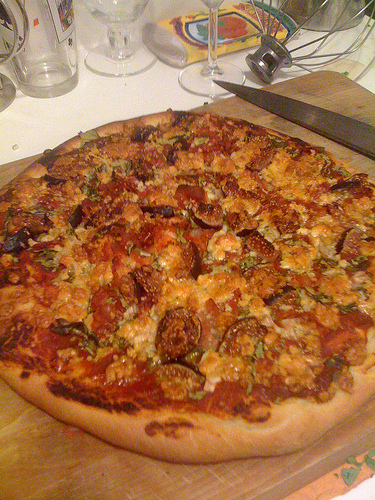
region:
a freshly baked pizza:
[0, 84, 372, 492]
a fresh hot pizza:
[1, 98, 373, 482]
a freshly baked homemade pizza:
[0, 90, 373, 486]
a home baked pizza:
[1, 71, 370, 485]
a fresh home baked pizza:
[2, 96, 371, 483]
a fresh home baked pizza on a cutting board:
[1, 109, 373, 481]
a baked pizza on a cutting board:
[0, 104, 372, 493]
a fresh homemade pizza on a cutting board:
[0, 99, 373, 462]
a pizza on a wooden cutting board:
[0, 109, 373, 477]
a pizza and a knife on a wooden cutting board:
[1, 53, 371, 440]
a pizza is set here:
[7, 111, 365, 463]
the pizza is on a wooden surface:
[4, 53, 365, 492]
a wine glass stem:
[180, 2, 247, 98]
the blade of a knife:
[212, 74, 369, 162]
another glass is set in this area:
[84, 0, 158, 75]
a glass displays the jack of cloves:
[10, 5, 79, 105]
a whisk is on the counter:
[248, 3, 371, 78]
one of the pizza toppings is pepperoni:
[96, 271, 198, 359]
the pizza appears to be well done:
[43, 162, 344, 383]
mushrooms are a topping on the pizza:
[185, 198, 229, 239]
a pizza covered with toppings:
[28, 233, 364, 407]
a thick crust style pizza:
[16, 353, 355, 467]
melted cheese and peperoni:
[102, 260, 262, 371]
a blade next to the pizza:
[211, 67, 370, 154]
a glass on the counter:
[14, 1, 95, 91]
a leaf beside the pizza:
[322, 449, 373, 482]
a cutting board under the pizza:
[18, 407, 273, 498]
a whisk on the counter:
[251, 3, 345, 83]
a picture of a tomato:
[150, 6, 272, 61]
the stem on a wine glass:
[203, 2, 235, 105]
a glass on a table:
[74, 7, 160, 96]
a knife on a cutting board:
[215, 59, 373, 144]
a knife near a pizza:
[207, 59, 343, 166]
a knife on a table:
[192, 46, 367, 211]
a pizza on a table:
[41, 68, 363, 449]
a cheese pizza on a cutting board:
[41, 166, 286, 427]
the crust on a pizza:
[55, 348, 311, 449]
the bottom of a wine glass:
[184, 20, 256, 89]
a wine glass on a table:
[169, 1, 259, 118]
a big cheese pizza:
[23, 91, 355, 444]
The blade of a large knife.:
[210, 69, 373, 152]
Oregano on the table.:
[339, 449, 373, 485]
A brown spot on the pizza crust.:
[136, 414, 196, 440]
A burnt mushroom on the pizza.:
[147, 303, 201, 363]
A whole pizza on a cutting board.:
[4, 114, 372, 469]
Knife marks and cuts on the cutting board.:
[41, 448, 227, 498]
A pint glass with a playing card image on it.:
[7, 1, 84, 94]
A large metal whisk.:
[244, 0, 371, 86]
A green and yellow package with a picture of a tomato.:
[149, 11, 302, 65]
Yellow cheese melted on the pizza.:
[269, 158, 297, 197]